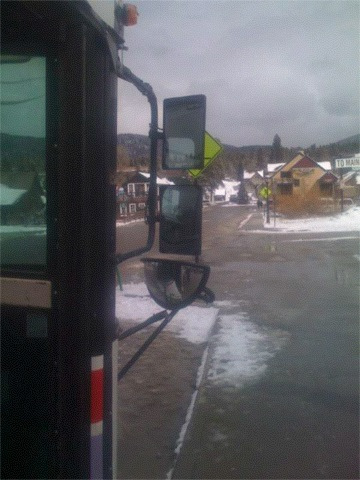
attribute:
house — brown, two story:
[258, 144, 346, 220]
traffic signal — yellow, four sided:
[255, 181, 276, 199]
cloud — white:
[232, 74, 312, 125]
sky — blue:
[154, 19, 356, 89]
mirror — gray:
[157, 93, 205, 168]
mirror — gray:
[159, 183, 202, 250]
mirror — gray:
[146, 257, 206, 305]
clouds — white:
[236, 54, 321, 128]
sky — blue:
[200, 29, 314, 98]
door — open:
[0, 0, 94, 479]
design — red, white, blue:
[80, 332, 128, 479]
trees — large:
[253, 131, 285, 165]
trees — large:
[306, 140, 332, 158]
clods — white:
[209, 17, 286, 80]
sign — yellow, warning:
[176, 122, 222, 180]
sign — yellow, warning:
[259, 185, 273, 198]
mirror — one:
[164, 95, 209, 171]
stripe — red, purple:
[84, 352, 117, 473]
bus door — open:
[2, 2, 107, 478]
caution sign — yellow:
[257, 183, 274, 223]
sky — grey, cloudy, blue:
[89, 1, 356, 150]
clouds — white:
[183, 22, 357, 148]